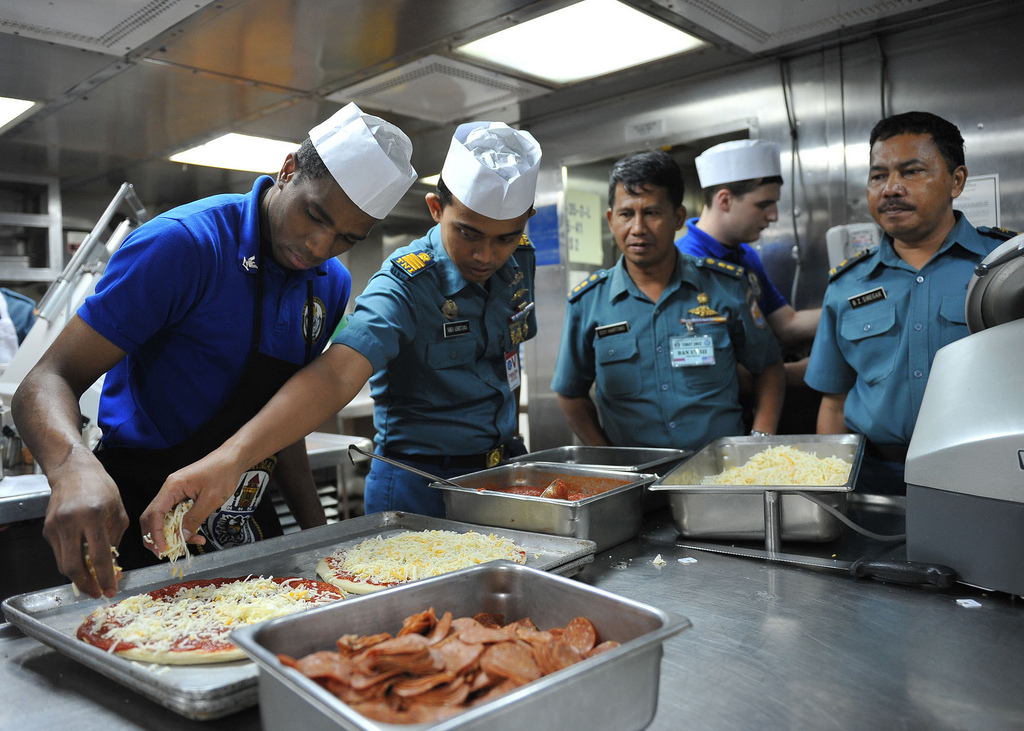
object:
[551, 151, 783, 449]
man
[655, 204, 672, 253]
cheek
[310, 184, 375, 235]
forehead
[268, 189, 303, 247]
cheek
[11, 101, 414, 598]
man